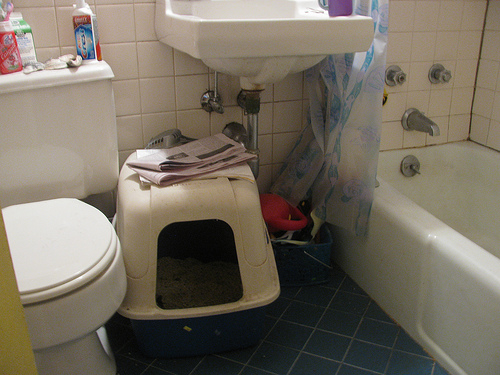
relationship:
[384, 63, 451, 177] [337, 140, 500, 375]
fixtures on bathtub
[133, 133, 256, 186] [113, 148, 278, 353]
newspapers on litter box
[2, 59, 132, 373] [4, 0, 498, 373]
toilet in bathroom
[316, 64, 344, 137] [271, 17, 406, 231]
pattern on curtain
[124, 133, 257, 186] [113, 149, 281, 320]
newspapers on box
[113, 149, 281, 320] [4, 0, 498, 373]
box in bathroom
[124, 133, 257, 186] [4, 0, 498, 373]
newspapers in bathroom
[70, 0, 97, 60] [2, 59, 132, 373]
toothpaste on toilet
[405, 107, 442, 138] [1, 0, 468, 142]
silver faucet on wall